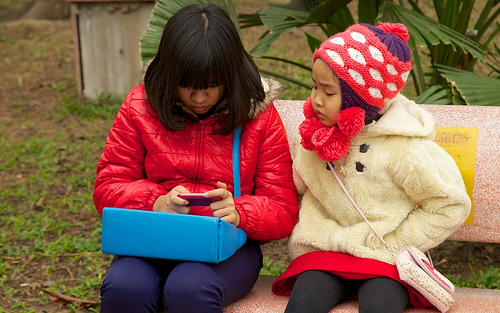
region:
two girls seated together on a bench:
[90, 2, 498, 309]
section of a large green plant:
[138, 1, 498, 106]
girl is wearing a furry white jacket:
[287, 93, 471, 258]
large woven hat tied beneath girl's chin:
[299, 20, 411, 158]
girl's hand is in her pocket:
[360, 223, 406, 258]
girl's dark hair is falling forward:
[141, 1, 261, 131]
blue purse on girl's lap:
[100, 205, 245, 260]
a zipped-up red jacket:
[94, 85, 299, 239]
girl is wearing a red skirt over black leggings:
[272, 253, 431, 311]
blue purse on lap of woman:
[91, 209, 258, 264]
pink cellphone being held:
[153, 179, 232, 211]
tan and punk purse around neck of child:
[390, 239, 462, 310]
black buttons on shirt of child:
[347, 141, 377, 177]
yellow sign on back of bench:
[423, 123, 488, 229]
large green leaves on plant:
[424, 3, 497, 105]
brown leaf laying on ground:
[22, 279, 102, 309]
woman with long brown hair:
[54, 12, 276, 311]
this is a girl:
[88, 22, 263, 304]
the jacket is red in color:
[148, 143, 198, 189]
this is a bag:
[113, 218, 226, 266]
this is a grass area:
[8, 128, 78, 249]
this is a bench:
[454, 107, 498, 139]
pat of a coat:
[345, 239, 357, 257]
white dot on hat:
[349, 30, 366, 45]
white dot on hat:
[368, 42, 380, 66]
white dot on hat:
[386, 58, 398, 75]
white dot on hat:
[400, 69, 410, 81]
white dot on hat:
[326, 33, 346, 48]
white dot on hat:
[345, 43, 367, 68]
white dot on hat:
[369, 65, 381, 83]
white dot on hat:
[382, 79, 397, 92]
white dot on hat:
[323, 46, 345, 66]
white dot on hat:
[348, 68, 367, 86]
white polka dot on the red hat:
[323, 43, 341, 68]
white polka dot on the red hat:
[342, 45, 365, 65]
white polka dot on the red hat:
[369, 65, 383, 83]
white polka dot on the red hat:
[365, 84, 382, 99]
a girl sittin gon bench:
[238, 27, 493, 304]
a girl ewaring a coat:
[288, 92, 498, 257]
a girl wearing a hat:
[320, 25, 416, 150]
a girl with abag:
[286, 135, 476, 301]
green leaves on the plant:
[418, 55, 448, 95]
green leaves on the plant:
[406, 6, 487, 69]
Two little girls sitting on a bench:
[83, 1, 483, 302]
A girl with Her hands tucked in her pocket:
[287, 25, 471, 307]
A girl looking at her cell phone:
[125, 6, 256, 220]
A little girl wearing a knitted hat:
[290, 16, 419, 164]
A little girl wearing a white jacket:
[286, 20, 468, 266]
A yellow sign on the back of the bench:
[435, 122, 482, 162]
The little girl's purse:
[393, 237, 461, 309]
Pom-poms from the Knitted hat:
[299, 111, 366, 161]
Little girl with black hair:
[143, 5, 267, 138]